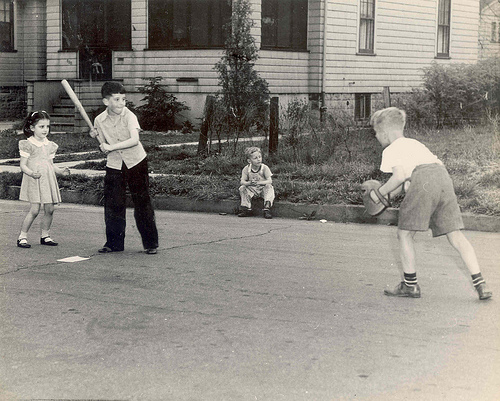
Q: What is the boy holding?
A: A bat.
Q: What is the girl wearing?
A: A dress.